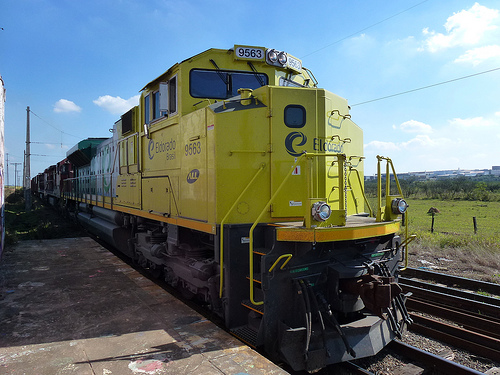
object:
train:
[25, 35, 422, 375]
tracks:
[305, 259, 498, 375]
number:
[196, 141, 203, 155]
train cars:
[60, 139, 97, 220]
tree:
[446, 172, 474, 201]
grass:
[360, 170, 499, 247]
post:
[428, 214, 436, 233]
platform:
[0, 233, 288, 375]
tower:
[22, 105, 36, 212]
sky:
[3, 1, 499, 176]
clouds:
[421, 1, 499, 70]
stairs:
[240, 225, 280, 317]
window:
[187, 65, 273, 101]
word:
[155, 137, 177, 153]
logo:
[281, 129, 309, 159]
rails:
[215, 154, 304, 309]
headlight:
[310, 200, 335, 222]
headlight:
[390, 196, 411, 216]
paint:
[21, 259, 103, 343]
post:
[470, 214, 481, 234]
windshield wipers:
[208, 58, 229, 85]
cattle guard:
[277, 290, 420, 371]